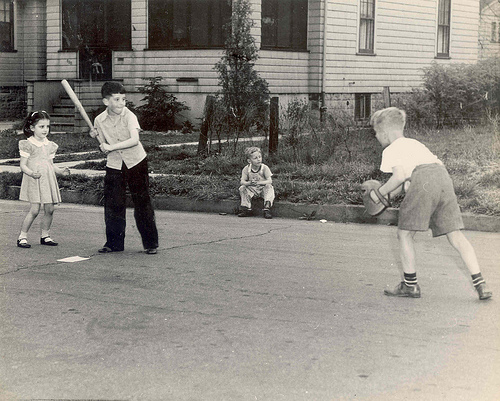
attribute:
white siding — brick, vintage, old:
[115, 51, 222, 58]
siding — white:
[258, 48, 306, 57]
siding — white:
[113, 48, 230, 59]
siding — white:
[112, 62, 234, 72]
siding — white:
[262, 83, 307, 98]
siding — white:
[134, 25, 271, 115]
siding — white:
[118, 0, 305, 91]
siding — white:
[136, 65, 209, 73]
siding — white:
[255, 64, 309, 70]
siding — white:
[261, 68, 303, 73]